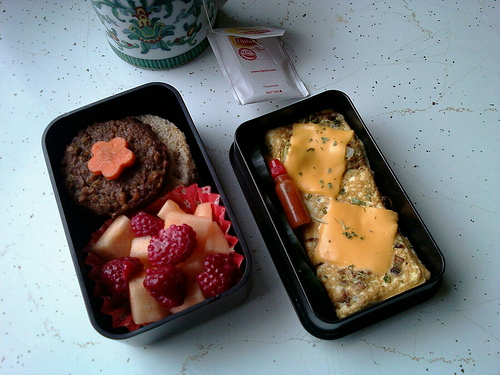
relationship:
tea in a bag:
[204, 21, 307, 105] [205, 23, 307, 105]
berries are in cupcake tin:
[101, 216, 233, 300] [84, 182, 248, 333]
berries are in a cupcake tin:
[101, 216, 233, 300] [84, 182, 248, 333]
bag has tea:
[205, 23, 307, 105] [204, 21, 307, 105]